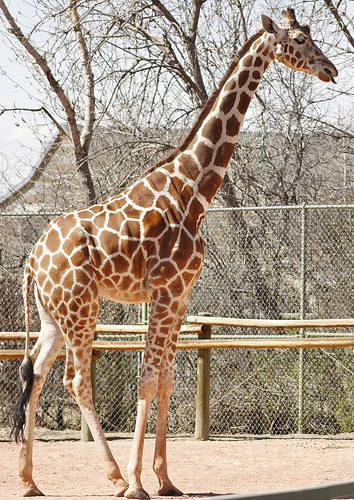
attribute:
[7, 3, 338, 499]
giraffe — large, standing, tall, cute, beautiful, wild, big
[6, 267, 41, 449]
tail — low, hanging, black, tan, brown, hairy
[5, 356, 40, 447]
hair — black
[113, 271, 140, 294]
spot — brown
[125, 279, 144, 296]
spot — brown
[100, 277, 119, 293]
spot — brown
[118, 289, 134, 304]
spot — brown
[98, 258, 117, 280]
spot — brown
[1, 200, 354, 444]
fence — wire, chain link, metal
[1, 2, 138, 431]
tree — leafless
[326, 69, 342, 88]
tongue — sticking out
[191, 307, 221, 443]
fence post — wooden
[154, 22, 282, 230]
neck — long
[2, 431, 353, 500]
ground — bare, dusty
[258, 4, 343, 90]
head — high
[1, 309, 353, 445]
fence — wooden